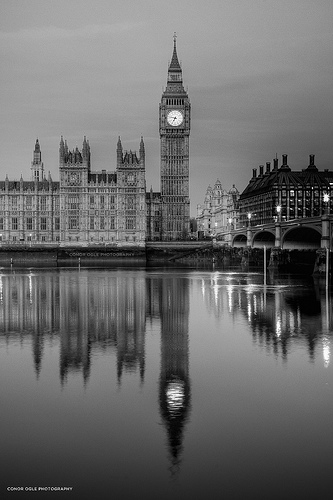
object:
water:
[1, 267, 333, 499]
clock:
[166, 109, 184, 127]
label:
[5, 484, 73, 492]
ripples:
[248, 317, 327, 364]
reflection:
[0, 268, 333, 467]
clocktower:
[159, 32, 192, 240]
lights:
[213, 221, 217, 229]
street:
[2, 241, 211, 246]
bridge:
[203, 212, 332, 251]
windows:
[314, 191, 318, 199]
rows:
[273, 185, 330, 193]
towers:
[58, 133, 66, 167]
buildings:
[58, 133, 146, 248]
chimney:
[308, 152, 315, 169]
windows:
[12, 216, 17, 231]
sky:
[0, 0, 333, 215]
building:
[195, 179, 240, 234]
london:
[1, 1, 332, 499]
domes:
[212, 179, 223, 191]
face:
[166, 109, 183, 125]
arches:
[231, 228, 248, 247]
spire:
[166, 29, 184, 72]